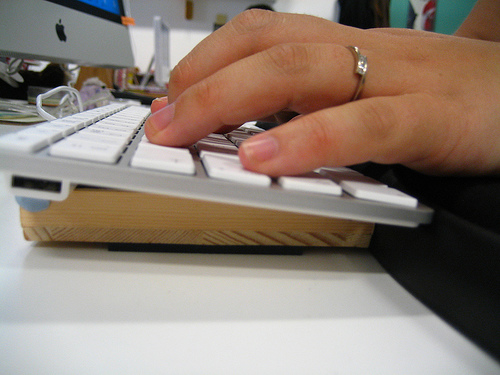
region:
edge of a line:
[251, 305, 282, 342]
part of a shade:
[230, 300, 257, 332]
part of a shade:
[240, 260, 261, 286]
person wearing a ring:
[345, 37, 377, 102]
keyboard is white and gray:
[6, 89, 436, 252]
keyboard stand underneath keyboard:
[12, 188, 371, 255]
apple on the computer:
[49, 13, 75, 49]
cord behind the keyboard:
[32, 78, 87, 123]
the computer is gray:
[0, 0, 141, 73]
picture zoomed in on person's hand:
[1, 0, 498, 374]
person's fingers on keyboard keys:
[141, 7, 498, 197]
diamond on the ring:
[349, 37, 371, 98]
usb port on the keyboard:
[5, 172, 66, 200]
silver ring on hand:
[346, 45, 368, 99]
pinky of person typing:
[242, 96, 422, 171]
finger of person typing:
[147, 48, 384, 148]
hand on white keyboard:
[140, 23, 497, 182]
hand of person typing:
[147, 6, 498, 183]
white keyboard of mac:
[1, 100, 433, 224]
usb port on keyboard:
[8, 170, 65, 201]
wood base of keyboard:
[8, 184, 373, 254]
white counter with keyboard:
[0, 241, 455, 372]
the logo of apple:
[49, 17, 76, 42]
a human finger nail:
[147, 106, 174, 131]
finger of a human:
[238, 92, 415, 175]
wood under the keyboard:
[20, 188, 374, 250]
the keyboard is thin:
[5, 100, 427, 226]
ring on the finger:
[349, 43, 367, 101]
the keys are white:
[4, 101, 416, 206]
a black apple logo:
[55, 18, 65, 42]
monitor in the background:
[152, 16, 170, 87]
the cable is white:
[38, 86, 82, 119]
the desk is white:
[2, 125, 498, 374]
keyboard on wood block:
[0, 102, 436, 245]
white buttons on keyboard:
[2, 102, 416, 204]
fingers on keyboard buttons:
[0, 11, 494, 177]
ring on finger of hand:
[142, 9, 497, 173]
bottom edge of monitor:
[2, 1, 132, 63]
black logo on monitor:
[52, 15, 67, 44]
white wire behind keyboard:
[32, 81, 83, 121]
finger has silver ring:
[117, 20, 439, 170]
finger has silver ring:
[300, 15, 405, 160]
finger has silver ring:
[222, 5, 399, 190]